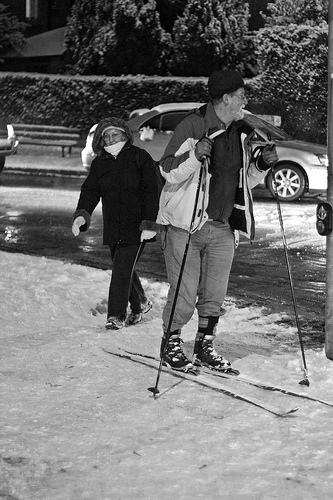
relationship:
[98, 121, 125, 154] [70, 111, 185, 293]
head of person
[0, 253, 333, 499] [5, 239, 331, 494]
snow on ground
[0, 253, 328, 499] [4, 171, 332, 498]
snow on ground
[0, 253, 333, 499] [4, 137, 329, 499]
snow on ground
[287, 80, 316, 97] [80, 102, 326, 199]
leaf behind car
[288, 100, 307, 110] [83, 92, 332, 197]
leaf behind car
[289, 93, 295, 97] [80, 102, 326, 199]
leaf behind car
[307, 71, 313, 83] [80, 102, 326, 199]
leaf behind car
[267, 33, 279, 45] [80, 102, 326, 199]
leaf behind car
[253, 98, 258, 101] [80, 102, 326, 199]
leaf behind car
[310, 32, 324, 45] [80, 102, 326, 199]
leaf behind car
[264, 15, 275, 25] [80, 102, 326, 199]
leaf behind car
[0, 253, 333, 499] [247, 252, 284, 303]
snow on ground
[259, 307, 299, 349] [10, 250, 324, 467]
snow on ground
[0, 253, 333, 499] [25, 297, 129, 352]
snow on ground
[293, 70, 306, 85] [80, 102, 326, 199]
leaf behind car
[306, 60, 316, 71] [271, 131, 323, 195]
leaf behind car